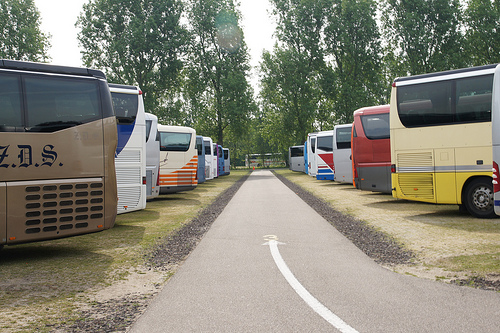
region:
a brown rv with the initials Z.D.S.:
[2, 57, 119, 249]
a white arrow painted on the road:
[262, 233, 359, 331]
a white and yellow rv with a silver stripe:
[388, 58, 494, 214]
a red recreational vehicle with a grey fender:
[350, 104, 391, 194]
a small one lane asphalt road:
[118, 166, 498, 331]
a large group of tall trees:
[80, 0, 495, 168]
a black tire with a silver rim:
[462, 174, 494, 220]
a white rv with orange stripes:
[160, 124, 198, 195]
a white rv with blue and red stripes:
[315, 131, 337, 182]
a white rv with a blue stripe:
[109, 80, 146, 219]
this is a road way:
[170, 172, 385, 331]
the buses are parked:
[6, 49, 492, 209]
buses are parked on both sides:
[5, 21, 495, 266]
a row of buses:
[3, 11, 240, 228]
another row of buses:
[272, 57, 497, 222]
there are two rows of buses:
[0, 28, 498, 238]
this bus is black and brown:
[0, 48, 134, 249]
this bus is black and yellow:
[384, 53, 496, 204]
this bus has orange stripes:
[159, 120, 213, 193]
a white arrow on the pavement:
[244, 226, 355, 331]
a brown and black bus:
[0, 55, 114, 246]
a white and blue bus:
[108, 80, 149, 217]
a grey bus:
[145, 109, 164, 202]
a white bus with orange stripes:
[158, 121, 198, 194]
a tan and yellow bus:
[389, 64, 496, 213]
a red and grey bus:
[353, 98, 396, 192]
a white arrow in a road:
[260, 237, 361, 331]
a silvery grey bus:
[332, 121, 358, 187]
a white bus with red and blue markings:
[314, 129, 337, 181]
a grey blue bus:
[193, 134, 206, 180]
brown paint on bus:
[74, 138, 88, 165]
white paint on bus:
[135, 130, 140, 142]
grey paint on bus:
[152, 146, 157, 160]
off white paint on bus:
[171, 156, 182, 161]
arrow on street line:
[261, 239, 288, 246]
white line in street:
[285, 265, 300, 287]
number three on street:
[262, 231, 280, 243]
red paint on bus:
[358, 143, 371, 153]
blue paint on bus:
[321, 168, 329, 175]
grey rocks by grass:
[311, 197, 331, 214]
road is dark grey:
[209, 153, 364, 325]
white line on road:
[240, 211, 349, 328]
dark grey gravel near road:
[297, 173, 402, 285]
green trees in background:
[104, 1, 381, 142]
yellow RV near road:
[382, 87, 495, 205]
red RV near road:
[335, 107, 393, 192]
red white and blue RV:
[306, 134, 343, 190]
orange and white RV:
[162, 121, 197, 188]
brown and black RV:
[0, 88, 107, 243]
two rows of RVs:
[45, 72, 485, 246]